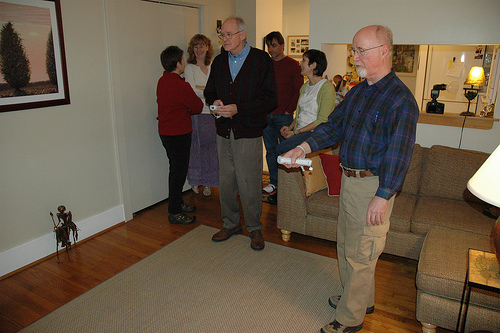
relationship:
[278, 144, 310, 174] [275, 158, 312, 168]
hand holding controller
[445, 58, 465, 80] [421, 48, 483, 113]
paper attached to fridge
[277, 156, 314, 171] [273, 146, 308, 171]
controller in hand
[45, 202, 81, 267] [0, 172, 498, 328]
figurine on floor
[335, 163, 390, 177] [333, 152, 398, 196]
belt around waist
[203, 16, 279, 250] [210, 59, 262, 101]
man wearing sweater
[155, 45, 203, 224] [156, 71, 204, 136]
people wearing shirt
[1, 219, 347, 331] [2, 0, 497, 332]
carpet in room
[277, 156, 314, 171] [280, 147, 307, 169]
controller in hand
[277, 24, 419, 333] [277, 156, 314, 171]
man playing controller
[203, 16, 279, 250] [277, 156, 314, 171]
man playing controller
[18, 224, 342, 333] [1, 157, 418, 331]
carpet on floor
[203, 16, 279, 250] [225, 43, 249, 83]
man wearing shirt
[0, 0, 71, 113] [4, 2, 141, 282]
painting hanging on wall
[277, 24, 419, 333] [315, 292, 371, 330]
man wearing shoes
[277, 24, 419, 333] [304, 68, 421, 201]
man wearing blue shirt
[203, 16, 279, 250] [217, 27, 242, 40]
man wearing glasses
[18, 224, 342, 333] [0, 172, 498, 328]
carpet on floor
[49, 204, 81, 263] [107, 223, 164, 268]
figurine on floor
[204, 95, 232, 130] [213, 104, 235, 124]
remote in hand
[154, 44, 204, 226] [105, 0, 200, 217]
people around door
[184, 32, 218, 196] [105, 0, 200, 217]
people around door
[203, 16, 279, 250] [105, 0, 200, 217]
man around door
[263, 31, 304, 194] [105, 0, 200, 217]
man around door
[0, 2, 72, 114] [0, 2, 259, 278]
painting on wall